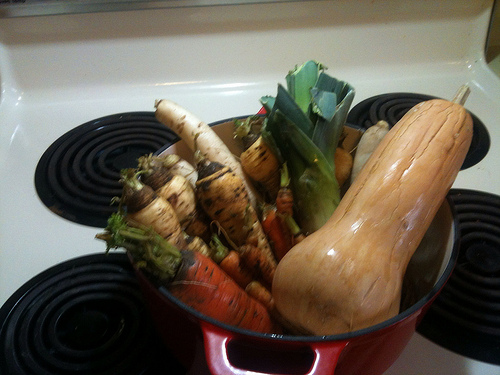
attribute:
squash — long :
[262, 80, 482, 333]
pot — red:
[123, 91, 477, 373]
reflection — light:
[160, 62, 268, 102]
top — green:
[100, 211, 177, 286]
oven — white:
[5, 6, 493, 373]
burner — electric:
[340, 85, 489, 168]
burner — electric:
[398, 182, 498, 363]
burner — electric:
[2, 246, 215, 368]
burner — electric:
[31, 107, 193, 231]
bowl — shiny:
[110, 104, 459, 370]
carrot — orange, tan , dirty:
[131, 222, 287, 333]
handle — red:
[192, 323, 343, 374]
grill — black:
[35, 100, 183, 218]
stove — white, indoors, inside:
[3, 13, 499, 369]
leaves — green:
[266, 58, 357, 205]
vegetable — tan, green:
[278, 83, 471, 330]